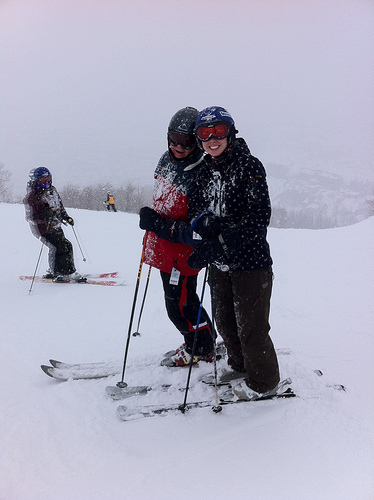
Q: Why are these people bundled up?
A: They are skiing in the snow.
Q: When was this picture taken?
A: In the winter.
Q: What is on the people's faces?
A: Goggles.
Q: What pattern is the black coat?
A: Black with white polka dots.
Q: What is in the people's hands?
A: Ski poles.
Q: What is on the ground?
A: Snow.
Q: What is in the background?
A: A mountain.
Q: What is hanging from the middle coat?
A: A ski tag.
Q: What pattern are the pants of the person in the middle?
A: Black with a red stripe.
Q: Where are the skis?
A: Feet.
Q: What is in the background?
A: Mountain.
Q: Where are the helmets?
A: Heads.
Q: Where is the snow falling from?
A: The sky.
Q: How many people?
A: 4.